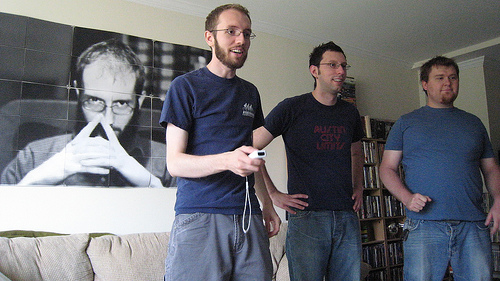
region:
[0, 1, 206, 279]
photo on wall above couch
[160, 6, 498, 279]
three men in room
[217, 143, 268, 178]
game control in hand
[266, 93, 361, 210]
red words on dirt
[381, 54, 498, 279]
man in blue jeans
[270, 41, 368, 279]
man with hands on hips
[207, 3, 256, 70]
man with beard on face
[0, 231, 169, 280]
two pillows of couch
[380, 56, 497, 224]
man in blue shirt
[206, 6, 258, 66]
glasses on man's face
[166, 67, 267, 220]
the man is wearing a t shirt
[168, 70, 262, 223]
the t shirt is blue in color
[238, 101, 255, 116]
the t shirt has a graphic print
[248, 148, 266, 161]
the man is holding a remote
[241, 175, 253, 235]
the remote has a strap attached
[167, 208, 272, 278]
the man is wearing grey pants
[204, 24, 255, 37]
the man is wearing glasses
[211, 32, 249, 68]
the man is wearing a beard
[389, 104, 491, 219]
the man is wearing a t shirt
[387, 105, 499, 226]
the t shirt is blue in color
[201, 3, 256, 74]
Man wearing clear glasses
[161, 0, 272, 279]
Man holding game control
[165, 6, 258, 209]
Man wearing blue t-shirt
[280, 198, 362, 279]
Man wearing blue jeans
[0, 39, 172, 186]
Man with glasses on picture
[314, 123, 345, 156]
Red writings on t-shirt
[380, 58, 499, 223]
Fat man with blue t-shirt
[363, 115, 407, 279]
Books arranged on shelves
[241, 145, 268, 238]
White control of game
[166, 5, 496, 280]
Three men standing in a room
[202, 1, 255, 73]
Facial hair on man's face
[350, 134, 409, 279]
Many books on shelves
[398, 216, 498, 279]
A pair of blue jeans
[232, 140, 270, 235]
White game controller in a hand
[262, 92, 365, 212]
Red writing on a dark shirt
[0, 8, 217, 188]
Man on a large photograph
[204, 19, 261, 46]
Glasses covering a man's eyes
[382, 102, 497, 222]
A blue colored shirt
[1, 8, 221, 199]
Large photo on the wall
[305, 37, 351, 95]
Dark brown hair on man's head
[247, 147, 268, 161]
Controller for game console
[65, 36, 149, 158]
Picture of man wearing glasses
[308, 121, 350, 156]
Red writing on blue tee shirt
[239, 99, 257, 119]
White writing on blue tee shirt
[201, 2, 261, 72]
Man's face with beard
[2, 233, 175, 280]
Two white pillows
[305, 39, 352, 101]
Head of man wearing glasses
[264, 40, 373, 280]
Man with his hands on his hips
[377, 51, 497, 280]
Man making a fist with his right hand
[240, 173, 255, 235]
Strao attached to game controller